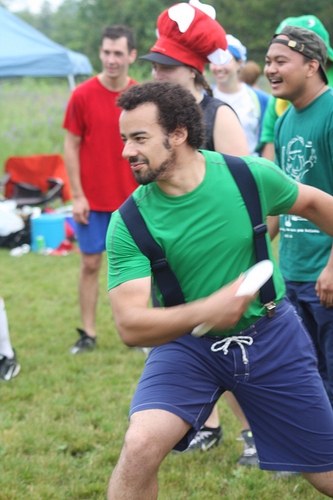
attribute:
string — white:
[209, 326, 256, 375]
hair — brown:
[129, 81, 191, 115]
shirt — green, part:
[125, 177, 290, 326]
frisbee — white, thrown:
[238, 238, 312, 333]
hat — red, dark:
[163, 20, 246, 46]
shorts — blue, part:
[152, 313, 286, 430]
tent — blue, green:
[17, 20, 146, 159]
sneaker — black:
[60, 301, 123, 356]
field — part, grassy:
[21, 283, 120, 444]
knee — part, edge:
[118, 431, 191, 449]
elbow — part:
[90, 334, 200, 360]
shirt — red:
[65, 61, 123, 156]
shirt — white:
[211, 67, 292, 166]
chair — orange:
[19, 132, 64, 195]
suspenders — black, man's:
[121, 199, 282, 289]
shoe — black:
[71, 313, 100, 358]